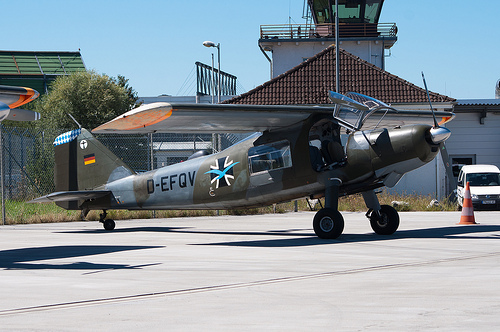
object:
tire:
[312, 207, 344, 239]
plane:
[29, 87, 454, 238]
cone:
[456, 181, 480, 225]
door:
[306, 129, 343, 168]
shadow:
[254, 224, 329, 255]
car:
[458, 163, 500, 211]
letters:
[149, 171, 194, 198]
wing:
[32, 189, 107, 203]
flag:
[81, 155, 98, 166]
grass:
[382, 195, 439, 211]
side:
[449, 114, 494, 149]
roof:
[215, 45, 454, 105]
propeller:
[417, 70, 459, 204]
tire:
[369, 207, 400, 234]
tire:
[101, 218, 116, 231]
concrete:
[403, 214, 488, 283]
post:
[336, 12, 337, 93]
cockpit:
[308, 121, 349, 161]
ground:
[49, 217, 454, 314]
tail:
[52, 128, 133, 191]